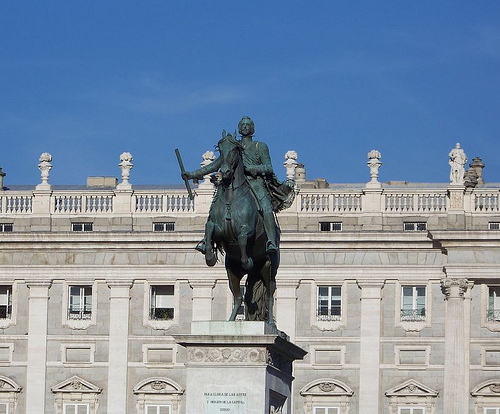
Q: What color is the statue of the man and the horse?
A: Green.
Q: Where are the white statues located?
A: At the top of the building.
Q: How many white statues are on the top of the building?
A: Six.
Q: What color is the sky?
A: Blue.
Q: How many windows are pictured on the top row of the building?
A: Six.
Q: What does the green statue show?
A: A man riding a horse.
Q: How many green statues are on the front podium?
A: One.